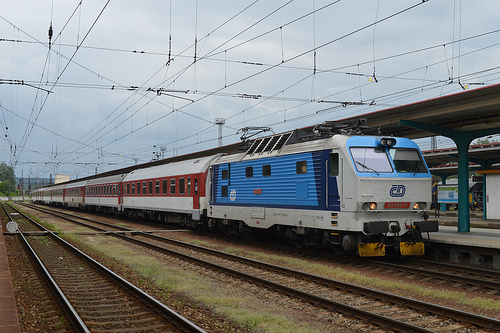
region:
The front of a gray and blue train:
[341, 132, 438, 259]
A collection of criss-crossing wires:
[183, 25, 385, 109]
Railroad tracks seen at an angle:
[26, 238, 156, 323]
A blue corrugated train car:
[207, 157, 338, 208]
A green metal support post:
[451, 143, 476, 233]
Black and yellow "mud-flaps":
[356, 233, 431, 260]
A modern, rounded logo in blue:
[387, 180, 412, 200]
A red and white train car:
[121, 167, 208, 217]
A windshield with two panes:
[348, 139, 430, 177]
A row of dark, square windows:
[121, 177, 198, 197]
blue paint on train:
[210, 164, 327, 203]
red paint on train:
[117, 183, 202, 195]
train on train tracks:
[39, 144, 411, 250]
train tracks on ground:
[26, 238, 102, 322]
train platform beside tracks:
[446, 202, 487, 247]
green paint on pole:
[451, 125, 477, 226]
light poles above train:
[8, 65, 138, 100]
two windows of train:
[346, 144, 423, 179]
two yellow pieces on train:
[358, 245, 425, 261]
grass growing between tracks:
[113, 242, 189, 329]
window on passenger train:
[387, 140, 424, 171]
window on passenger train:
[345, 136, 395, 173]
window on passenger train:
[290, 153, 310, 179]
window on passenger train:
[255, 157, 275, 182]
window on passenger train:
[216, 163, 233, 178]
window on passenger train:
[216, 181, 234, 200]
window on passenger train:
[176, 168, 188, 195]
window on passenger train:
[146, 173, 164, 196]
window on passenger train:
[132, 175, 149, 197]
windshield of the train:
[348, 145, 429, 171]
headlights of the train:
[358, 191, 421, 216]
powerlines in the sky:
[164, 42, 310, 102]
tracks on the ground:
[245, 262, 363, 309]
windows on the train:
[104, 182, 199, 201]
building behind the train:
[50, 175, 72, 185]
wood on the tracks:
[102, 295, 133, 315]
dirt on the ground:
[22, 300, 64, 325]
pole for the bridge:
[452, 140, 484, 232]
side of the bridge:
[406, 104, 474, 129]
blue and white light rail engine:
[204, 132, 448, 250]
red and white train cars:
[30, 163, 214, 215]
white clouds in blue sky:
[37, 9, 88, 56]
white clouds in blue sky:
[322, 43, 377, 74]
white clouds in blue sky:
[100, 78, 177, 120]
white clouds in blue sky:
[47, 103, 98, 128]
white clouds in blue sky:
[80, 65, 167, 107]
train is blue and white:
[213, 138, 432, 240]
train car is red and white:
[122, 154, 212, 217]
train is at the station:
[28, 115, 458, 262]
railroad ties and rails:
[7, 201, 162, 327]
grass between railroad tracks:
[62, 222, 236, 312]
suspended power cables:
[9, 3, 485, 168]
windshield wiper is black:
[355, 154, 380, 176]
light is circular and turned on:
[367, 198, 377, 210]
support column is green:
[455, 132, 474, 234]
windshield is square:
[350, 144, 392, 175]